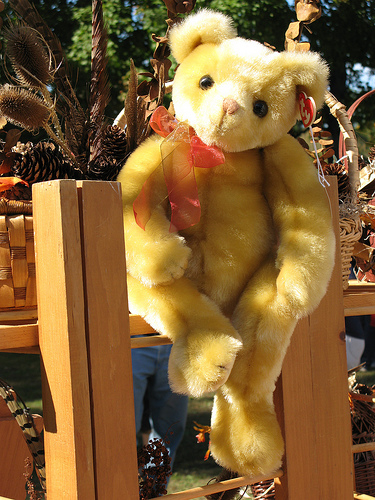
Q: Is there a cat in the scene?
A: No, there are no cats.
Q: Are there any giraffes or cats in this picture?
A: No, there are no cats or giraffes.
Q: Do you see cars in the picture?
A: No, there are no cars.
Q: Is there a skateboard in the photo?
A: No, there are no skateboards.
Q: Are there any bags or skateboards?
A: No, there are no skateboards or bags.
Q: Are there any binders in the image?
A: No, there are no binders.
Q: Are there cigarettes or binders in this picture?
A: No, there are no binders or cigarettes.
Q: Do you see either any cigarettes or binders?
A: No, there are no binders or cigarettes.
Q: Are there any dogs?
A: No, there are no dogs.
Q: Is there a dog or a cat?
A: No, there are no dogs or cats.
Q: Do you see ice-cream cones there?
A: No, there are no ice-cream cones.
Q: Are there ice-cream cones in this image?
A: No, there are no ice-cream cones.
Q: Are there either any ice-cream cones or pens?
A: No, there are no ice-cream cones or pens.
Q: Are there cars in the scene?
A: No, there are no cars.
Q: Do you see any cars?
A: No, there are no cars.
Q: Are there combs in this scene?
A: No, there are no combs.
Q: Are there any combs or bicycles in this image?
A: No, there are no combs or bicycles.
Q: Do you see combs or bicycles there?
A: No, there are no combs or bicycles.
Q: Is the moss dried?
A: Yes, the moss is dried.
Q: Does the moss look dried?
A: Yes, the moss is dried.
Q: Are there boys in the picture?
A: No, there are no boys.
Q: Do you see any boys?
A: No, there are no boys.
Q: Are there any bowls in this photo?
A: No, there are no bowls.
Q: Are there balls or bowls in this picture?
A: No, there are no bowls or balls.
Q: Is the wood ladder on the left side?
A: Yes, the ladder is on the left of the image.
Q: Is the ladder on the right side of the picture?
A: No, the ladder is on the left of the image.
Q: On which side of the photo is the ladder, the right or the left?
A: The ladder is on the left of the image.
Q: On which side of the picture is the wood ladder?
A: The ladder is on the left of the image.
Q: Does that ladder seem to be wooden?
A: Yes, the ladder is wooden.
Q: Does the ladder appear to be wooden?
A: Yes, the ladder is wooden.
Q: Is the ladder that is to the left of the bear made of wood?
A: Yes, the ladder is made of wood.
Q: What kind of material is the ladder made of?
A: The ladder is made of wood.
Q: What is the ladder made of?
A: The ladder is made of wood.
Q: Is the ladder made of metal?
A: No, the ladder is made of wood.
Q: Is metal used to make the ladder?
A: No, the ladder is made of wood.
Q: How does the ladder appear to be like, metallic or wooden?
A: The ladder is wooden.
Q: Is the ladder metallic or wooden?
A: The ladder is wooden.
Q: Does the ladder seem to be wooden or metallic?
A: The ladder is wooden.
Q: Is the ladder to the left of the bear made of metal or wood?
A: The ladder is made of wood.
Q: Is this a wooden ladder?
A: Yes, this is a wooden ladder.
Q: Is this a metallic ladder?
A: No, this is a wooden ladder.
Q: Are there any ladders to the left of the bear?
A: Yes, there is a ladder to the left of the bear.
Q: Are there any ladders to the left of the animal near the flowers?
A: Yes, there is a ladder to the left of the bear.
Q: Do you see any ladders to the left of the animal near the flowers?
A: Yes, there is a ladder to the left of the bear.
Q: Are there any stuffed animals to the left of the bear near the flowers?
A: No, there is a ladder to the left of the bear.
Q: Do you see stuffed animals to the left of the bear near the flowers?
A: No, there is a ladder to the left of the bear.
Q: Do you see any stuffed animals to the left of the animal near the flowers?
A: No, there is a ladder to the left of the bear.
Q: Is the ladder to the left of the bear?
A: Yes, the ladder is to the left of the bear.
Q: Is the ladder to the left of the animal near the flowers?
A: Yes, the ladder is to the left of the bear.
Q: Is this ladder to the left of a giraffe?
A: No, the ladder is to the left of the bear.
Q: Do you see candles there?
A: No, there are no candles.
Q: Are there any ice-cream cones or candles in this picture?
A: No, there are no candles or ice-cream cones.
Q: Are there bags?
A: No, there are no bags.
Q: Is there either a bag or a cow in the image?
A: No, there are no bags or cows.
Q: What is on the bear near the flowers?
A: The tag is on the bear.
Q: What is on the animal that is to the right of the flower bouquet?
A: The tag is on the bear.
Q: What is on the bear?
A: The tag is on the bear.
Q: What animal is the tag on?
A: The tag is on the bear.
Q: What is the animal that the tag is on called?
A: The animal is a bear.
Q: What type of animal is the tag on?
A: The tag is on the bear.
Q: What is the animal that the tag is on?
A: The animal is a bear.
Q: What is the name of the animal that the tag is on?
A: The animal is a bear.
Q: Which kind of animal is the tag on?
A: The tag is on the bear.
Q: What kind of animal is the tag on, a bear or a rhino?
A: The tag is on a bear.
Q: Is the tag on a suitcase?
A: No, the tag is on the bear.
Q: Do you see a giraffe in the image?
A: No, there are no giraffes.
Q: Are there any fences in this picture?
A: Yes, there is a fence.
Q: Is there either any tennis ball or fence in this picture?
A: Yes, there is a fence.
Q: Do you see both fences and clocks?
A: No, there is a fence but no clocks.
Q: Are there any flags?
A: No, there are no flags.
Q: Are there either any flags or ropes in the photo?
A: No, there are no flags or ropes.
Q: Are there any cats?
A: No, there are no cats.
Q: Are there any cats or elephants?
A: No, there are no cats or elephants.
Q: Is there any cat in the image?
A: No, there are no cats.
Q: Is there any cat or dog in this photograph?
A: No, there are no cats or dogs.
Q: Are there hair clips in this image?
A: No, there are no hair clips.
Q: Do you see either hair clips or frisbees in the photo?
A: No, there are no hair clips or frisbees.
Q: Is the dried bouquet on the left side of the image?
A: Yes, the flower bouquet is on the left of the image.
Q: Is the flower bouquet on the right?
A: No, the flower bouquet is on the left of the image.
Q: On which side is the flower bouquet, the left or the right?
A: The flower bouquet is on the left of the image.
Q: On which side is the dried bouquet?
A: The flower bouquet is on the left of the image.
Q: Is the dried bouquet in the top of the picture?
A: Yes, the flower bouquet is in the top of the image.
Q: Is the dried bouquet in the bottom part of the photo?
A: No, the bouquet is in the top of the image.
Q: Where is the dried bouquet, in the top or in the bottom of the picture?
A: The flower bouquet is in the top of the image.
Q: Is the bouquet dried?
A: Yes, the bouquet is dried.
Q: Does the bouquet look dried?
A: Yes, the bouquet is dried.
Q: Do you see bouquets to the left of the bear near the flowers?
A: Yes, there is a bouquet to the left of the bear.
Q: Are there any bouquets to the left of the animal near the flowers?
A: Yes, there is a bouquet to the left of the bear.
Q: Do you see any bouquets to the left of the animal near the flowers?
A: Yes, there is a bouquet to the left of the bear.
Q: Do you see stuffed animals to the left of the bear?
A: No, there is a bouquet to the left of the bear.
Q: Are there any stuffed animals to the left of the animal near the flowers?
A: No, there is a bouquet to the left of the bear.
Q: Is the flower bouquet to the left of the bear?
A: Yes, the flower bouquet is to the left of the bear.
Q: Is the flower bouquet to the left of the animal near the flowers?
A: Yes, the flower bouquet is to the left of the bear.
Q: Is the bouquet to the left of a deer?
A: No, the bouquet is to the left of the bear.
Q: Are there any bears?
A: Yes, there is a bear.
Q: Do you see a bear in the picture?
A: Yes, there is a bear.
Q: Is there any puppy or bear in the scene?
A: Yes, there is a bear.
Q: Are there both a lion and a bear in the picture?
A: No, there is a bear but no lions.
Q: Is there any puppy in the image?
A: No, there are no puppies.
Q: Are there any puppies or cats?
A: No, there are no puppies or cats.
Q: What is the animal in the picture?
A: The animal is a bear.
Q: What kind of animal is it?
A: The animal is a bear.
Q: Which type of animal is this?
A: This is a bear.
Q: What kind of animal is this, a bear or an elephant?
A: This is a bear.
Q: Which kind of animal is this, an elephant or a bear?
A: This is a bear.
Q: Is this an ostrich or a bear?
A: This is a bear.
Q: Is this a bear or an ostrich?
A: This is a bear.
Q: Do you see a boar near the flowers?
A: No, there is a bear near the flowers.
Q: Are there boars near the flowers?
A: No, there is a bear near the flowers.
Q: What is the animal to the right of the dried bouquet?
A: The animal is a bear.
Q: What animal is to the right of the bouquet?
A: The animal is a bear.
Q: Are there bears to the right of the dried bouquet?
A: Yes, there is a bear to the right of the flower bouquet.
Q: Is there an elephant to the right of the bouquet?
A: No, there is a bear to the right of the bouquet.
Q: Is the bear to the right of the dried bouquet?
A: Yes, the bear is to the right of the bouquet.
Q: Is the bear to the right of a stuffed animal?
A: No, the bear is to the right of the bouquet.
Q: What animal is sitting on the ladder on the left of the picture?
A: The bear is sitting on the ladder.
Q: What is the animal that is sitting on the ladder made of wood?
A: The animal is a bear.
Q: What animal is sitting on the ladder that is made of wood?
A: The animal is a bear.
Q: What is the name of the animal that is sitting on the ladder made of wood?
A: The animal is a bear.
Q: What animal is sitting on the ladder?
A: The animal is a bear.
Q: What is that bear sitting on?
A: The bear is sitting on the ladder.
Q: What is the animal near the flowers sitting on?
A: The bear is sitting on the ladder.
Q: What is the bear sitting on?
A: The bear is sitting on the ladder.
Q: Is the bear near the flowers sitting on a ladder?
A: Yes, the bear is sitting on a ladder.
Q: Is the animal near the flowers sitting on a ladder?
A: Yes, the bear is sitting on a ladder.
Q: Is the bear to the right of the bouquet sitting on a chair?
A: No, the bear is sitting on a ladder.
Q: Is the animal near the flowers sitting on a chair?
A: No, the bear is sitting on a ladder.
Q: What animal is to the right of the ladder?
A: The animal is a bear.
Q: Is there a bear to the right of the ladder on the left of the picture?
A: Yes, there is a bear to the right of the ladder.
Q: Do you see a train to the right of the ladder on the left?
A: No, there is a bear to the right of the ladder.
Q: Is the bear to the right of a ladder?
A: Yes, the bear is to the right of a ladder.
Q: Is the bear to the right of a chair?
A: No, the bear is to the right of a ladder.